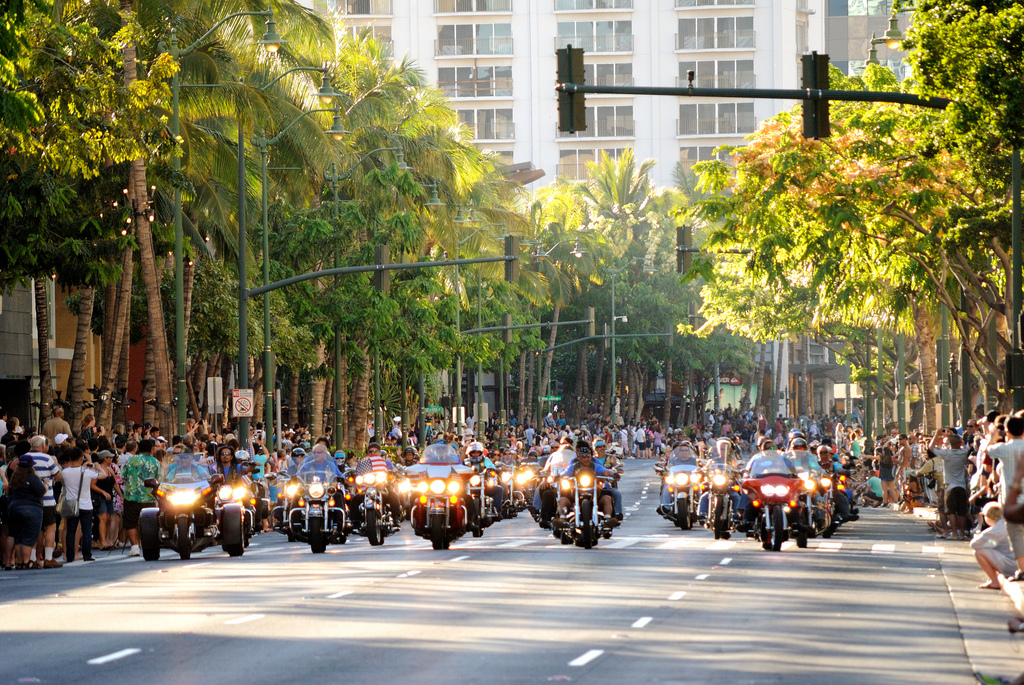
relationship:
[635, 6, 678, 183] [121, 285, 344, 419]
wall on building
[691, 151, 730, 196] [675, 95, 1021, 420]
leaves on tree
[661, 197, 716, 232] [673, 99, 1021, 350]
leaves on tree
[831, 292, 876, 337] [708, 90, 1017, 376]
leaves on tree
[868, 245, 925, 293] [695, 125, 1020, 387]
leaves on tree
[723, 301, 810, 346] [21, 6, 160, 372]
leaves on tree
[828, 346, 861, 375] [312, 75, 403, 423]
leaves on tree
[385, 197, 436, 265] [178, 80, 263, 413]
leaves on tree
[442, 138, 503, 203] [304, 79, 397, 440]
leaves on tree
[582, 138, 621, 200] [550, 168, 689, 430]
leaves on tree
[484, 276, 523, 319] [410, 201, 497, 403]
leaves on tree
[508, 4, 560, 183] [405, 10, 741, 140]
wall on building